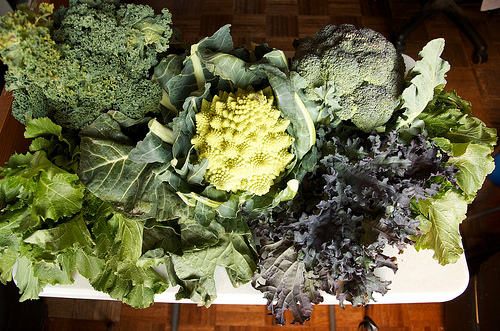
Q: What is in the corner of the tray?
A: Green broccoli.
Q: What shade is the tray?
A: White.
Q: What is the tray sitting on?
A: Brown table.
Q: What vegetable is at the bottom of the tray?
A: Red cabbage.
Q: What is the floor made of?
A: Wood tiles.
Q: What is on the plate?
A: Variety of vegetables.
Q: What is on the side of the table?
A: Tray of vegetables.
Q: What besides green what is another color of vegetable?
A: Purple.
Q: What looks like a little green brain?
A: Broccoli.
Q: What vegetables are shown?
A: Cabbage and star fruit.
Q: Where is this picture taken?
A: A kitchen.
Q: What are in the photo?
A: Green veggies.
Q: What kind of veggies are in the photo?
A: Green leafy veggies.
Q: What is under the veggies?
A: A white board.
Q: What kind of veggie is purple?
A: The cabbage.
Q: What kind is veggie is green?
A: Kale.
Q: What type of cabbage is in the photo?
A: Green.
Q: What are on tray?
A: Veggies.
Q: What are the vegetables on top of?
A: A table.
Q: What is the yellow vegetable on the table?
A: Romanesco broccoli.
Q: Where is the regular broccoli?
A: Diagonal to the Romanesco broccoli.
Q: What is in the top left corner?
A: Kale.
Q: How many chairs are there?
A: One.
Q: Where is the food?
A: On the table.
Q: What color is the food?
A: Green.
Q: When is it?
A: Day time.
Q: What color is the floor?
A: Brown.